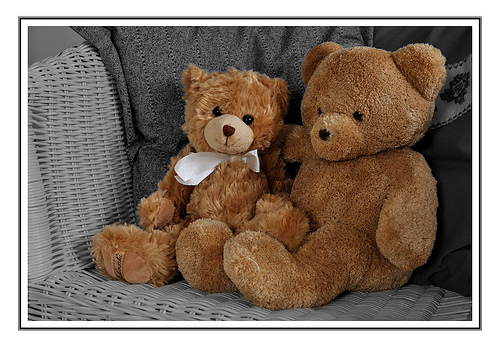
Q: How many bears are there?
A: Two.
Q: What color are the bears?
A: Brown.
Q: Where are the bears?
A: On a chair.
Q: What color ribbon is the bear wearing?
A: White.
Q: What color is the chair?
A: Grey.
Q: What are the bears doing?
A: Sitting down.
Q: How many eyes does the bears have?
A: Two.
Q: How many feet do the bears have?
A: Two.